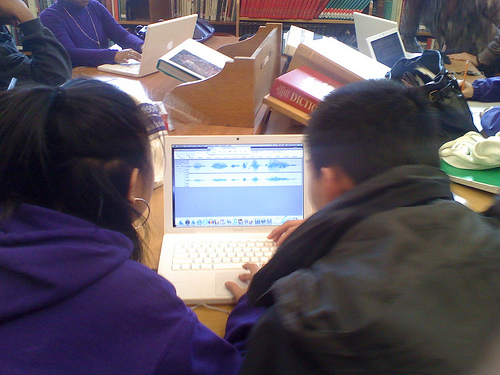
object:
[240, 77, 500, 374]
boy